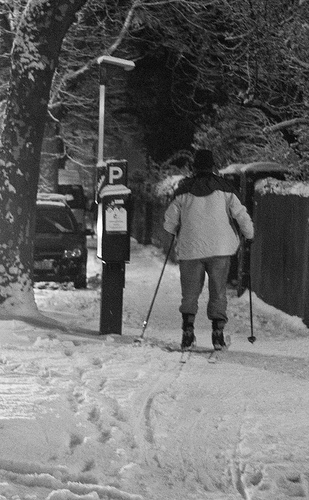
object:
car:
[30, 191, 87, 290]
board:
[208, 333, 232, 364]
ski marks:
[143, 345, 255, 499]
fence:
[129, 182, 308, 332]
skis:
[178, 335, 197, 363]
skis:
[207, 335, 232, 364]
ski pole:
[133, 234, 171, 341]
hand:
[167, 229, 178, 236]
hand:
[246, 236, 253, 243]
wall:
[133, 164, 308, 326]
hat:
[191, 148, 215, 170]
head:
[191, 149, 215, 171]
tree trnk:
[0, 0, 86, 324]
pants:
[178, 255, 229, 325]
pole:
[249, 238, 253, 340]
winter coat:
[163, 188, 254, 262]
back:
[173, 179, 239, 264]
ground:
[1, 234, 309, 500]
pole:
[97, 73, 107, 158]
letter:
[108, 165, 123, 184]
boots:
[180, 313, 226, 351]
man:
[161, 149, 255, 353]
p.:
[109, 164, 124, 185]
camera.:
[0, 149, 309, 499]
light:
[96, 54, 136, 87]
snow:
[0, 0, 309, 499]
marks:
[0, 337, 309, 499]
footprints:
[64, 339, 125, 499]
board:
[249, 191, 309, 328]